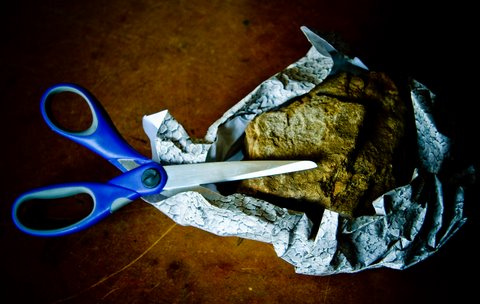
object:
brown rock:
[240, 63, 406, 220]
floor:
[0, 0, 480, 304]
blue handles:
[10, 84, 168, 239]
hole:
[16, 193, 95, 231]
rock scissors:
[12, 26, 468, 278]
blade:
[140, 185, 224, 204]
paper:
[138, 26, 474, 276]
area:
[99, 9, 242, 82]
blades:
[162, 158, 318, 190]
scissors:
[12, 86, 318, 238]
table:
[0, 0, 479, 304]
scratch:
[82, 222, 177, 292]